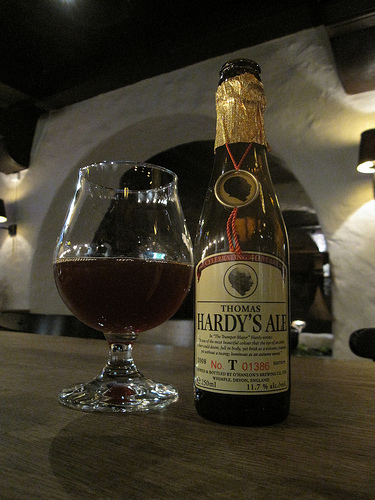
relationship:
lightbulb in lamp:
[358, 160, 370, 172] [355, 121, 373, 164]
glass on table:
[80, 164, 174, 419] [1, 385, 58, 423]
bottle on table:
[199, 151, 283, 420] [1, 385, 58, 423]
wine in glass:
[75, 253, 130, 278] [80, 164, 174, 419]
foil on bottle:
[234, 94, 252, 104] [199, 151, 283, 420]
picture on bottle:
[228, 262, 249, 303] [199, 151, 283, 420]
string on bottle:
[226, 146, 238, 161] [199, 151, 283, 420]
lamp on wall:
[355, 121, 373, 164] [283, 49, 312, 75]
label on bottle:
[189, 247, 262, 393] [199, 151, 283, 420]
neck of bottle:
[200, 104, 272, 148] [199, 151, 283, 420]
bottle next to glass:
[199, 151, 283, 420] [80, 164, 174, 419]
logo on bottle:
[201, 312, 262, 333] [199, 151, 283, 420]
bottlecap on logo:
[216, 53, 258, 70] [201, 312, 262, 333]